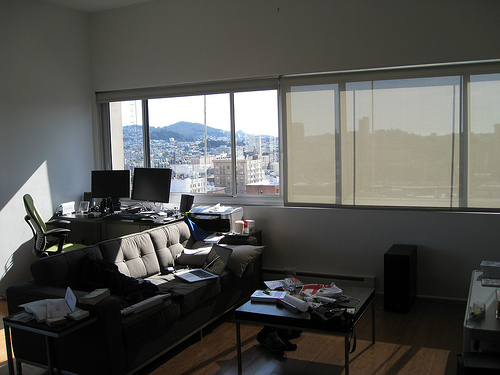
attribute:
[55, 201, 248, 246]
desk — messy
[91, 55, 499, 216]
window — open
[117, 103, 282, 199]
city view — clear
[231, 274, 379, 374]
coffee table — dirty, black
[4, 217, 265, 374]
couch — brown, grey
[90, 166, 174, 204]
computer monitors — off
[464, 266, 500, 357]
table — withe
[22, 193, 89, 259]
chair — lime green, green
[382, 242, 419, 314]
speaker — black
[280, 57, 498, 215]
curtains — cream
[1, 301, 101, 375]
end table — black